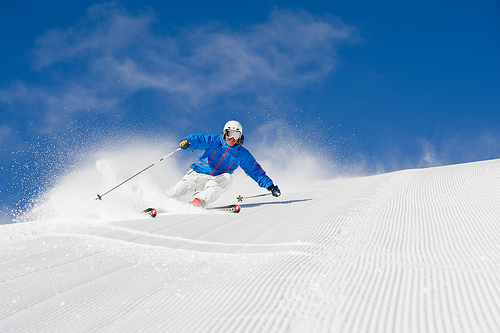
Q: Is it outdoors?
A: Yes, it is outdoors.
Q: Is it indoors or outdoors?
A: It is outdoors.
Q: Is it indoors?
A: No, it is outdoors.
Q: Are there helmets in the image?
A: Yes, there is a helmet.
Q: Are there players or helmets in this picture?
A: Yes, there is a helmet.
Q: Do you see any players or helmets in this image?
A: Yes, there is a helmet.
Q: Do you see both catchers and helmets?
A: No, there is a helmet but no catchers.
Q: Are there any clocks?
A: No, there are no clocks.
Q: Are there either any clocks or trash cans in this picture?
A: No, there are no clocks or trash cans.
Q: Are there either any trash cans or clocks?
A: No, there are no clocks or trash cans.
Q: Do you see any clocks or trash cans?
A: No, there are no clocks or trash cans.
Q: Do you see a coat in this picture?
A: Yes, there is a coat.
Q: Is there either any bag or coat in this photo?
A: Yes, there is a coat.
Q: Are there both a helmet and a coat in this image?
A: Yes, there are both a coat and a helmet.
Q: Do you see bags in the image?
A: No, there are no bags.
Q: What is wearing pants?
A: The coat is wearing pants.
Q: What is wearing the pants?
A: The coat is wearing pants.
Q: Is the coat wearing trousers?
A: Yes, the coat is wearing trousers.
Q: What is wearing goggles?
A: The coat is wearing goggles.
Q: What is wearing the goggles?
A: The coat is wearing goggles.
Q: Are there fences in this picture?
A: No, there are no fences.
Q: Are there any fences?
A: No, there are no fences.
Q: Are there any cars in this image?
A: No, there are no cars.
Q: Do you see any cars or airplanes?
A: No, there are no cars or airplanes.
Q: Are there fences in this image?
A: No, there are no fences.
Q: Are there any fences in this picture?
A: No, there are no fences.